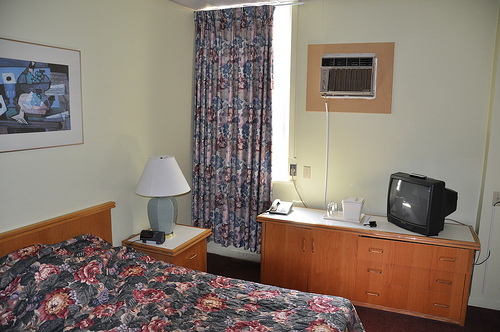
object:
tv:
[386, 172, 460, 238]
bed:
[1, 201, 363, 332]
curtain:
[190, 3, 285, 256]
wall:
[0, 1, 499, 319]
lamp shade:
[132, 152, 191, 198]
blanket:
[74, 262, 149, 318]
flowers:
[71, 258, 158, 287]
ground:
[431, 188, 446, 201]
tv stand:
[384, 171, 458, 240]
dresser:
[258, 205, 480, 326]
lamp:
[135, 155, 190, 238]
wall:
[401, 19, 463, 116]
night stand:
[120, 223, 213, 283]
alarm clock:
[139, 229, 165, 244]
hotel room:
[1, 0, 500, 332]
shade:
[132, 148, 194, 198]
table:
[120, 217, 212, 274]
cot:
[0, 200, 118, 261]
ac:
[319, 53, 378, 102]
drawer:
[356, 235, 467, 275]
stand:
[256, 203, 481, 328]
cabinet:
[259, 220, 361, 303]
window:
[266, 6, 292, 186]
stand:
[123, 223, 213, 273]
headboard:
[0, 200, 121, 280]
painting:
[0, 28, 84, 152]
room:
[0, 0, 500, 332]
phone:
[269, 198, 294, 215]